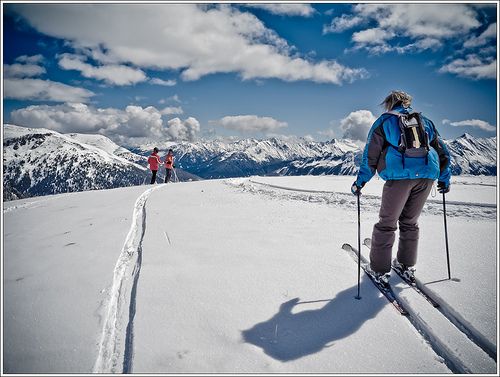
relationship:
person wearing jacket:
[348, 86, 458, 301] [352, 106, 452, 191]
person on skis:
[147, 144, 162, 183] [127, 172, 189, 192]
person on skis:
[162, 144, 175, 181] [127, 172, 189, 192]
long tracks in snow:
[91, 182, 149, 373] [2, 173, 498, 373]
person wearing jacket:
[143, 145, 164, 186] [144, 148, 164, 170]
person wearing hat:
[147, 144, 162, 183] [149, 145, 164, 155]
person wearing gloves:
[348, 86, 458, 301] [350, 180, 363, 195]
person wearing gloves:
[348, 86, 458, 301] [437, 182, 449, 193]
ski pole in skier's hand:
[347, 206, 371, 271] [346, 177, 369, 198]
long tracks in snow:
[94, 182, 166, 373] [143, 220, 312, 373]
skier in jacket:
[162, 147, 174, 183] [147, 150, 167, 169]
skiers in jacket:
[147, 147, 166, 182] [165, 152, 174, 165]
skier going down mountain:
[355, 90, 462, 319] [27, 166, 492, 374]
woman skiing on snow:
[349, 88, 456, 298] [2, 173, 498, 373]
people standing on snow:
[143, 144, 178, 183] [2, 173, 498, 373]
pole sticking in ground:
[315, 186, 382, 308] [136, 218, 478, 374]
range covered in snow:
[13, 100, 478, 211] [3, 122, 496, 196]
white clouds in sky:
[12, 10, 496, 83] [5, 3, 495, 145]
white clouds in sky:
[5, 55, 373, 139] [5, 3, 495, 145]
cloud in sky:
[148, 73, 177, 89] [5, 3, 495, 145]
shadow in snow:
[237, 272, 405, 362] [187, 210, 277, 270]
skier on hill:
[162, 147, 174, 183] [111, 144, 231, 216]